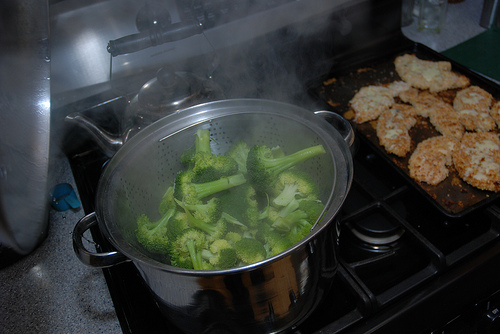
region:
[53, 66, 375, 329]
a pot on a stove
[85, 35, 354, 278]
steam over the pot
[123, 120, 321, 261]
broccoli in a pot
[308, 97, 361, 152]
right handle of pot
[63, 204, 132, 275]
left handle of pot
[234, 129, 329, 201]
a green piece of broccoli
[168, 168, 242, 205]
a green piece of broccoli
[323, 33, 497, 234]
chicken nuggets on tray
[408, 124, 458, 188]
a piece of chicken nugget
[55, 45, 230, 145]
a kettle color silver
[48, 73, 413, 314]
Pot full of steamed broccoli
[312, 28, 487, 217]
pan of fried chicken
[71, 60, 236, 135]
tea pot with tea in it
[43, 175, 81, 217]
blue cup for measuring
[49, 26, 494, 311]
black stove with food cooking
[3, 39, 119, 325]
the kitchen counter top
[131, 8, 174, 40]
black button to turn the stove on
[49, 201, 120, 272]
silver handle of the pot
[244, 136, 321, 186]
piece of broccoli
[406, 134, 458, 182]
piece of chicken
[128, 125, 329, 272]
Broccoli being cooked on the stove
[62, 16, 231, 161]
Kettle on the cooking stove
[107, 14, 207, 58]
black handle of the table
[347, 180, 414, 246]
Burner of the cooking stove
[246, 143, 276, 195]
leaf of the broccoli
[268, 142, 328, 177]
Stem of the broccoli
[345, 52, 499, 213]
Chicken nuggets on the cooking stove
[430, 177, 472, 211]
crumbs of the chicken nuggets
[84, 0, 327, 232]
White smoke caused by broccoli being cooked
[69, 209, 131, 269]
left handle of the cooking pot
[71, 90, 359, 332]
Nice shiny cooking pot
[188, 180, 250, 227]
Part of green broccoli spears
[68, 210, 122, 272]
Handle of cooking pot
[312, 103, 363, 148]
Handle of cook pot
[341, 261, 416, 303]
Part of top of cook stove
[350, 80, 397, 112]
Part of food being cooked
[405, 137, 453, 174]
Part f food being cooked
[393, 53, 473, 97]
Part of food being cooked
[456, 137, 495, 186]
Part of food being cooked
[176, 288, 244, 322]
Part of shiny pot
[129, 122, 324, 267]
brocolli in a pot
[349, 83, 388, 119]
breaded meat on a tray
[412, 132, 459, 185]
breaded meat on a tray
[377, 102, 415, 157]
breaded meat on a tray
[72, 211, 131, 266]
handle on a pot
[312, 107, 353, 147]
handle on a pot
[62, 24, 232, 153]
a metal kettle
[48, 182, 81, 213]
a blue measuring cup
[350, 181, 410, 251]
a burner on a stove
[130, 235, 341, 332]
reflection on a pot